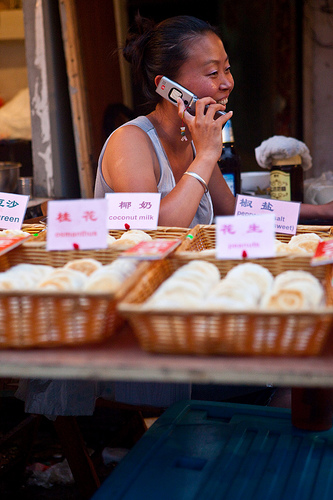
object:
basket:
[25, 223, 192, 256]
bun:
[124, 14, 151, 67]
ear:
[154, 76, 161, 90]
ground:
[11, 479, 52, 500]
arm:
[110, 145, 213, 227]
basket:
[118, 255, 333, 353]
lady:
[92, 17, 333, 229]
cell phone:
[153, 76, 228, 133]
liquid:
[290, 169, 303, 202]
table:
[0, 335, 330, 409]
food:
[149, 281, 202, 296]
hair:
[119, 12, 214, 117]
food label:
[213, 213, 276, 260]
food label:
[45, 198, 110, 252]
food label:
[102, 191, 161, 229]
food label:
[0, 193, 31, 233]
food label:
[235, 193, 300, 237]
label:
[270, 170, 291, 201]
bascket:
[175, 222, 331, 265]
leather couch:
[255, 134, 312, 170]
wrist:
[192, 153, 218, 164]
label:
[214, 212, 277, 260]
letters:
[261, 201, 274, 211]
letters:
[247, 223, 263, 232]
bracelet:
[184, 170, 209, 194]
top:
[273, 156, 301, 164]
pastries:
[211, 277, 256, 296]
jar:
[270, 156, 303, 202]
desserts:
[261, 281, 306, 313]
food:
[63, 258, 102, 269]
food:
[111, 236, 137, 251]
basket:
[3, 217, 46, 239]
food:
[0, 270, 18, 291]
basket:
[1, 247, 147, 347]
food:
[278, 243, 314, 258]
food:
[289, 233, 325, 247]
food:
[262, 283, 311, 309]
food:
[227, 263, 270, 279]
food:
[180, 258, 219, 274]